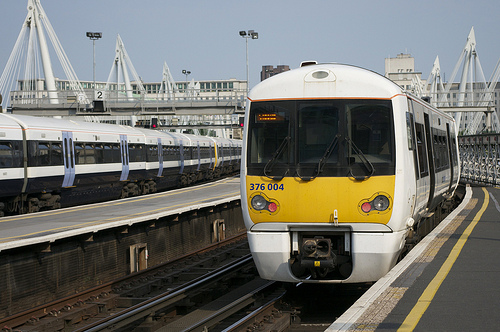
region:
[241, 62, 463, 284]
A mostly white train with yellow on the front.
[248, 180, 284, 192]
The number 376 004 on the front left of a train.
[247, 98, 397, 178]
Large dark front windshield of a train.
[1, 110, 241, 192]
A long white train with blue doors.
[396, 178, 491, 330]
A yellow line down the side of the walkway.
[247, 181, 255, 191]
The number 3 on the front of a yellow strip on a train.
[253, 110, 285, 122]
A black sign with orange LED letters on the upper left windshield of a train.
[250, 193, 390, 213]
Headlights on the front of a train.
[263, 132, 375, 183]
Black windshield wipers on the windshield of a train.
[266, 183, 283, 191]
004 on the front of a yellow strip on a train.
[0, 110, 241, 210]
A long white train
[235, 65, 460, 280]
A yellow and white train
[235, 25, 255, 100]
A very tall light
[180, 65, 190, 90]
A very tall light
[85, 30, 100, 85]
A very tall light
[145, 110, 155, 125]
A hanging red light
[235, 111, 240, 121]
A red light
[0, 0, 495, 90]
A clear blue sky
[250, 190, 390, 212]
headlights on a train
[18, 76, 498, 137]
A large white building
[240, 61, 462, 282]
yellow and white passenger train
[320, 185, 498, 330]
train platform with yellow caution line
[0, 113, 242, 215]
black and white striped passenger train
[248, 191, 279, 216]
pink and grey train car headlight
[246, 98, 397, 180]
dark window glass with black windshield wipers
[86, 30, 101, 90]
tall light post in the distance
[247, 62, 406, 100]
roof is white with orange trim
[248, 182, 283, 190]
blue number identifies train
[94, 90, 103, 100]
white square shape with black number 2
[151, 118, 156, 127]
red signal light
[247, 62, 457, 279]
a white and yellow silver railroad car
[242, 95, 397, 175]
the front window of a railroad car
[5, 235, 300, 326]
railroad tracks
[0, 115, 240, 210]
a white train with blue doors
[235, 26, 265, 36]
overhead lights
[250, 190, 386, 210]
two sets of lights on the front of a railroad car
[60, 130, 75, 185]
blue doors on the side of a railroad car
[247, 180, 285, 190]
a six digit number printed in blue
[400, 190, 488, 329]
a yellow line painted on a concrete platform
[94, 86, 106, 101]
the number 2 painted in black on a white sign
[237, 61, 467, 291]
yellow and white train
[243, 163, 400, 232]
yellow train front end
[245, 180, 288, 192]
passenger train identification number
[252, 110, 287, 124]
digital information sign in window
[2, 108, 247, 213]
long white passenger train on left of photo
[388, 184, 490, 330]
yellow safety boundary line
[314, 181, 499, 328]
yellow passenger train platform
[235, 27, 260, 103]
tall silver light pole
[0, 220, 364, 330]
track for passenger train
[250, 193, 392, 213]
passenger train head lights